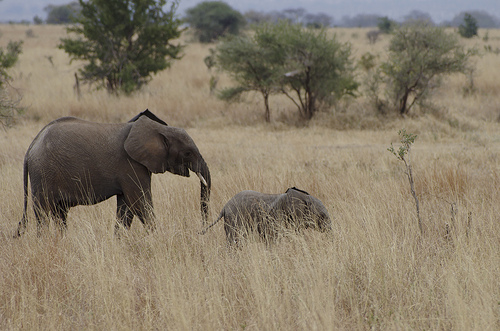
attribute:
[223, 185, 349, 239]
baby — walking, grey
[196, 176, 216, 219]
trunk — brown, large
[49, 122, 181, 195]
elephant — walking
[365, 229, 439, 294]
grass — dry, brown